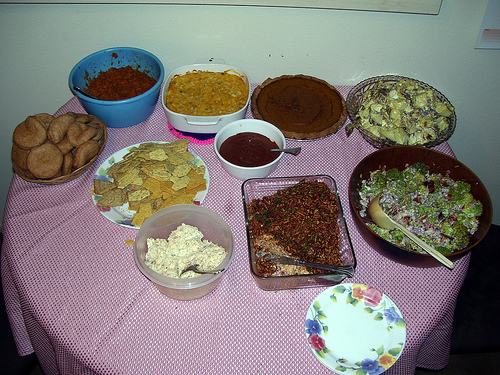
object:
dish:
[88, 141, 212, 230]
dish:
[133, 204, 236, 300]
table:
[3, 86, 473, 374]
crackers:
[97, 188, 125, 206]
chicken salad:
[143, 223, 227, 278]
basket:
[11, 111, 109, 187]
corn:
[163, 70, 246, 116]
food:
[302, 229, 333, 255]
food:
[93, 143, 206, 228]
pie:
[248, 74, 348, 140]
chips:
[148, 148, 169, 162]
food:
[257, 77, 342, 134]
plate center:
[333, 312, 377, 351]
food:
[247, 179, 345, 277]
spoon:
[255, 252, 356, 275]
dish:
[239, 173, 358, 291]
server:
[365, 199, 454, 271]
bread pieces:
[47, 114, 76, 145]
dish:
[161, 62, 250, 134]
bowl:
[346, 74, 457, 150]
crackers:
[107, 162, 124, 178]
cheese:
[141, 176, 162, 196]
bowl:
[212, 118, 287, 181]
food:
[382, 126, 410, 144]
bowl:
[65, 47, 165, 128]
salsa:
[81, 66, 154, 101]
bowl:
[347, 145, 494, 267]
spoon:
[368, 195, 454, 269]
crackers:
[92, 176, 118, 194]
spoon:
[271, 147, 301, 156]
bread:
[26, 142, 65, 179]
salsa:
[232, 134, 262, 154]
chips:
[170, 163, 191, 178]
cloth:
[0, 81, 472, 374]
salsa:
[103, 74, 133, 97]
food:
[400, 187, 471, 225]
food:
[297, 182, 326, 204]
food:
[197, 75, 232, 103]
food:
[218, 132, 281, 167]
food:
[63, 153, 74, 173]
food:
[359, 98, 378, 110]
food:
[73, 140, 101, 169]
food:
[360, 163, 483, 254]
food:
[352, 81, 452, 145]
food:
[164, 72, 250, 116]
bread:
[11, 116, 48, 151]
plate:
[303, 282, 406, 374]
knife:
[256, 252, 356, 278]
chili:
[84, 66, 156, 101]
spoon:
[180, 264, 225, 276]